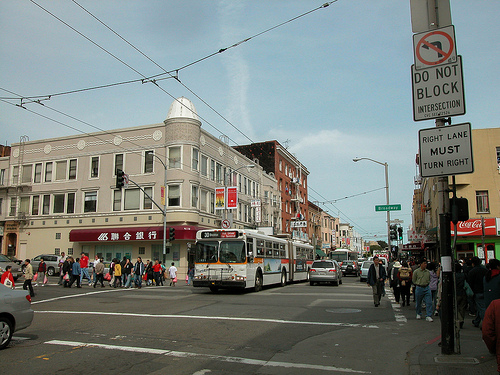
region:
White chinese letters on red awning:
[88, 226, 161, 244]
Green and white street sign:
[371, 198, 410, 215]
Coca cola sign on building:
[444, 210, 499, 237]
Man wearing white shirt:
[364, 255, 387, 309]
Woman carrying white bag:
[0, 262, 19, 296]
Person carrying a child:
[393, 259, 415, 308]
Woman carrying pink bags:
[32, 252, 53, 292]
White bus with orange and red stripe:
[181, 230, 315, 287]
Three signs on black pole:
[408, 26, 473, 257]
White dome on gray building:
[151, 82, 211, 183]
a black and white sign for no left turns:
[401, 26, 492, 74]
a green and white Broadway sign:
[347, 194, 422, 228]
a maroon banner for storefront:
[71, 226, 196, 251]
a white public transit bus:
[187, 216, 344, 290]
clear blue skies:
[272, 50, 360, 105]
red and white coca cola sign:
[447, 211, 498, 236]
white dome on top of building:
[170, 86, 226, 132]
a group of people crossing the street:
[21, 239, 178, 290]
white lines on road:
[204, 303, 310, 344]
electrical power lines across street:
[121, 43, 223, 122]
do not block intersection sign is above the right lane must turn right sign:
[408, 58, 468, 121]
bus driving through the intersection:
[197, 227, 317, 292]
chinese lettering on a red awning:
[69, 228, 189, 241]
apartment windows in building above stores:
[111, 188, 156, 209]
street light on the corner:
[351, 154, 399, 276]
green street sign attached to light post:
[373, 203, 407, 213]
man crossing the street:
[365, 255, 392, 312]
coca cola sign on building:
[442, 219, 499, 234]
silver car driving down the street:
[308, 258, 343, 288]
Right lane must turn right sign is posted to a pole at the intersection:
[416, 128, 476, 178]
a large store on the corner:
[6, 127, 281, 274]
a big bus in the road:
[192, 224, 314, 286]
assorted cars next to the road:
[314, 236, 368, 288]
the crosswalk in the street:
[25, 307, 400, 364]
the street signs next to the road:
[405, 4, 491, 359]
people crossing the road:
[64, 248, 174, 295]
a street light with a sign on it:
[356, 155, 403, 243]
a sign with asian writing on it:
[94, 224, 166, 241]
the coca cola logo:
[453, 219, 487, 234]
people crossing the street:
[361, 256, 491, 328]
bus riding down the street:
[195, 229, 324, 278]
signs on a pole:
[398, 21, 493, 209]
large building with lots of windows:
[42, 148, 217, 218]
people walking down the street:
[15, 246, 184, 276]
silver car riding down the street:
[4, 273, 54, 335]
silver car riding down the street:
[282, 254, 357, 372]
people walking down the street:
[353, 241, 435, 321]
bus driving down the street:
[322, 247, 359, 258]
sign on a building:
[456, 216, 495, 241]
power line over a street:
[82, 9, 288, 84]